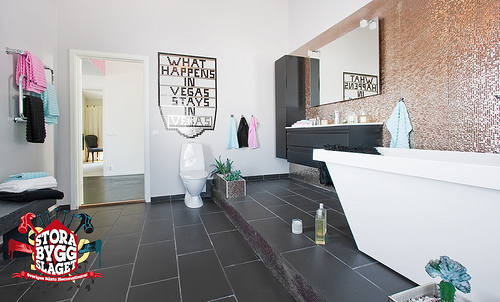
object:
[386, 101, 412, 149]
towel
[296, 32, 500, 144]
wall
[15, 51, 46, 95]
towel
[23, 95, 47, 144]
towel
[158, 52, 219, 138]
sign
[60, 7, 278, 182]
wall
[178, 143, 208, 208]
toilet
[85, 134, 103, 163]
chair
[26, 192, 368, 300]
floor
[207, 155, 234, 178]
plants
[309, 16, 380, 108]
mirror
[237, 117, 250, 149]
towels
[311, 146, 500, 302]
bathtub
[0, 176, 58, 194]
towels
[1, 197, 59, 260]
bench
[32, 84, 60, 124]
towels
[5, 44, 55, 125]
rack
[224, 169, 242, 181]
small plant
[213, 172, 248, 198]
pot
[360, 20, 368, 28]
lights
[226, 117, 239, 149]
towel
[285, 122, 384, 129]
counter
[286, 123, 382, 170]
cabinet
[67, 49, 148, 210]
door